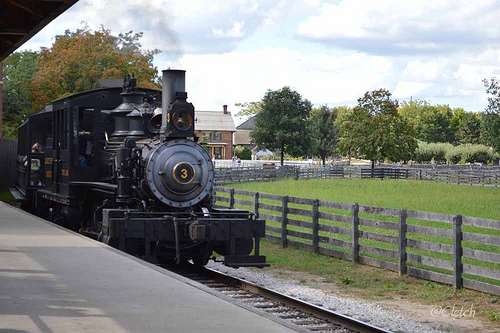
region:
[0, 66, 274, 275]
old fashioned train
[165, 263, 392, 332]
the train tracks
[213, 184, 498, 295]
grey colored fence beside tracks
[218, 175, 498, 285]
green grass inside corral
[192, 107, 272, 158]
red bricked house in background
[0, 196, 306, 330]
grey platform next to train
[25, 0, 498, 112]
white fluffy clouds in sky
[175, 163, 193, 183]
yellow 3 on front of train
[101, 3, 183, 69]
black smoke coming from train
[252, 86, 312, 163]
large dark green tree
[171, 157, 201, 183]
number 3 on front of train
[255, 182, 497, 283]
grey fence next to train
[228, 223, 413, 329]
gravel next to tracks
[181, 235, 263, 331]
railroad ties beneath train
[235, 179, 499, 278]
green field next to train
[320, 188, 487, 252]
grass is green and thick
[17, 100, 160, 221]
train has black engine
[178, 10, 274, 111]
sky is grey and cloudy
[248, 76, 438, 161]
tall trees behind fence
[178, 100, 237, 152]
brown building behind train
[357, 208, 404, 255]
slats on wooden fence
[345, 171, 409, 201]
grass in the enclosed fence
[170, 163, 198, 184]
number on the train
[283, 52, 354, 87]
clouds in the sky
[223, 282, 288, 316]
part of railroad track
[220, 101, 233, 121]
chimney on the roof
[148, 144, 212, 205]
front face of train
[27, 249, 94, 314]
sidewalk by the train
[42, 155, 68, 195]
side of the train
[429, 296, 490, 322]
wording on bottom right of picture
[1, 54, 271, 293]
a train on rails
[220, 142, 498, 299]
a green field has a fence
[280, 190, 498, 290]
fence is of wood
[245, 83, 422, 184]
trees near a fence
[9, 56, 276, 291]
a locomotive on rails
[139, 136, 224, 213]
number 3 in front of train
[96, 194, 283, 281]
bumper of train is black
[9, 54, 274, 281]
locomotive is black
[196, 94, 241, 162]
a house on back the train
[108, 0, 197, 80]
smote exit from locomotive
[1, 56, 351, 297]
Train on the tracks.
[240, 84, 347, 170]
Tree in the background.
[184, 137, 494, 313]
Fences around a field.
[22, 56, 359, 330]
Train with 3 on the front.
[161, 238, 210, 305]
Track under the train.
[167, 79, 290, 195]
Buildings in the background.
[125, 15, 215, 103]
Smoke coming from the train.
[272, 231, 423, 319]
Grass by the fence.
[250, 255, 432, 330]
Gravel on the tracks.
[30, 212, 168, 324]
Shadows on the concrete.